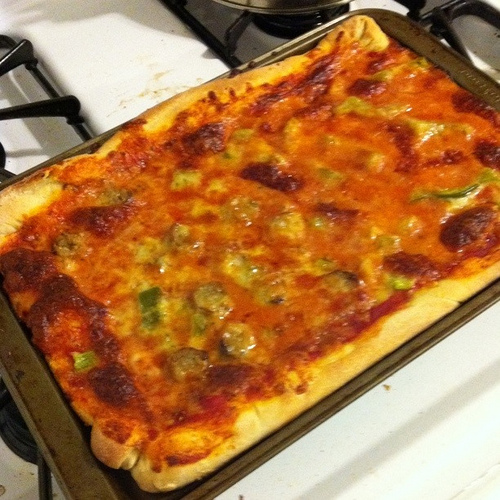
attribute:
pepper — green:
[135, 287, 169, 334]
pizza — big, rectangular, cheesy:
[0, 19, 500, 494]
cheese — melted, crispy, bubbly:
[4, 45, 499, 461]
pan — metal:
[0, 3, 495, 498]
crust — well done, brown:
[0, 14, 500, 492]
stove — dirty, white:
[0, 1, 497, 498]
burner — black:
[0, 26, 97, 191]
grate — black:
[161, 0, 353, 74]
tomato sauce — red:
[36, 45, 498, 394]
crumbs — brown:
[114, 68, 206, 111]